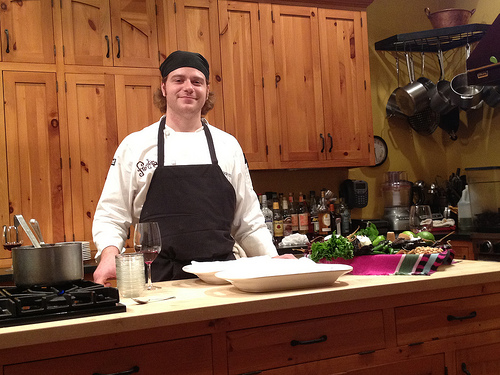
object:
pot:
[10, 241, 84, 288]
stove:
[0, 276, 126, 330]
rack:
[374, 21, 490, 54]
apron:
[134, 115, 236, 284]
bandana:
[159, 49, 210, 79]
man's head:
[160, 51, 211, 114]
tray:
[212, 263, 353, 293]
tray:
[182, 254, 293, 284]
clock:
[373, 134, 389, 168]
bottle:
[317, 190, 331, 236]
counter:
[269, 231, 474, 253]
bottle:
[296, 190, 309, 232]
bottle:
[272, 194, 284, 241]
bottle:
[279, 196, 293, 238]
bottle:
[338, 198, 351, 235]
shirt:
[93, 114, 277, 264]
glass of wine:
[133, 221, 163, 288]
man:
[92, 50, 298, 289]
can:
[116, 250, 146, 298]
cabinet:
[269, 0, 375, 169]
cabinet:
[58, 0, 163, 69]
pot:
[448, 72, 487, 109]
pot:
[428, 48, 460, 116]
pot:
[397, 48, 430, 117]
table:
[0, 257, 499, 373]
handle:
[447, 311, 477, 321]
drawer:
[394, 278, 499, 347]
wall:
[246, 0, 499, 221]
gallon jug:
[458, 184, 479, 231]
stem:
[147, 262, 152, 288]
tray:
[316, 249, 453, 276]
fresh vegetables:
[303, 220, 446, 261]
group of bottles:
[257, 189, 352, 243]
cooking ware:
[424, 6, 477, 30]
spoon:
[13, 213, 41, 249]